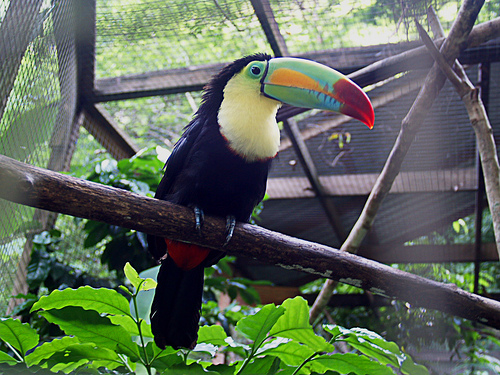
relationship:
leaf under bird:
[33, 285, 135, 320] [131, 47, 371, 366]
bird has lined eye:
[152, 41, 343, 308] [240, 54, 269, 78]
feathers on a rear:
[139, 51, 283, 354] [123, 207, 235, 274]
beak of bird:
[260, 50, 379, 133] [124, 52, 384, 362]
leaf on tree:
[33, 285, 135, 320] [18, 168, 337, 368]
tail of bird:
[155, 260, 205, 352] [124, 52, 384, 362]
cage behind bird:
[1, 0, 492, 321] [124, 52, 384, 362]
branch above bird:
[398, 16, 468, 86] [152, 41, 343, 308]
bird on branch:
[152, 41, 343, 308] [2, 147, 498, 341]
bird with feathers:
[152, 41, 343, 308] [154, 89, 260, 263]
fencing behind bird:
[63, 40, 450, 276] [117, 17, 365, 324]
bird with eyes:
[152, 41, 343, 308] [244, 41, 285, 114]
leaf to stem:
[33, 285, 135, 320] [113, 272, 173, 364]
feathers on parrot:
[147, 153, 244, 352] [98, 22, 393, 314]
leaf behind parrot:
[33, 285, 135, 320] [120, 80, 407, 306]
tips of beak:
[121, 210, 175, 330] [241, 43, 415, 184]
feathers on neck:
[139, 51, 283, 354] [207, 70, 377, 234]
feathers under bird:
[139, 51, 283, 354] [103, 28, 403, 335]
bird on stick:
[152, 41, 343, 308] [40, 152, 483, 341]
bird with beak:
[62, 27, 412, 356] [246, 24, 433, 203]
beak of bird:
[260, 50, 379, 133] [152, 41, 343, 308]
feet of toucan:
[181, 201, 244, 250] [114, 37, 379, 348]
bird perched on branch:
[152, 41, 343, 308] [45, 162, 448, 322]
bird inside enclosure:
[152, 41, 343, 308] [9, 3, 186, 107]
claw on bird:
[190, 207, 207, 241] [152, 41, 343, 308]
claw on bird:
[222, 214, 241, 245] [152, 41, 343, 308]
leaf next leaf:
[33, 285, 135, 320] [26, 337, 125, 366]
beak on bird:
[260, 50, 379, 133] [152, 41, 343, 308]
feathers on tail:
[139, 51, 283, 354] [147, 257, 216, 351]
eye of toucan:
[242, 57, 263, 79] [114, 37, 379, 348]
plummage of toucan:
[193, 157, 263, 207] [92, 53, 399, 343]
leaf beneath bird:
[33, 285, 135, 320] [152, 41, 343, 308]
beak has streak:
[260, 50, 379, 133] [266, 60, 328, 99]